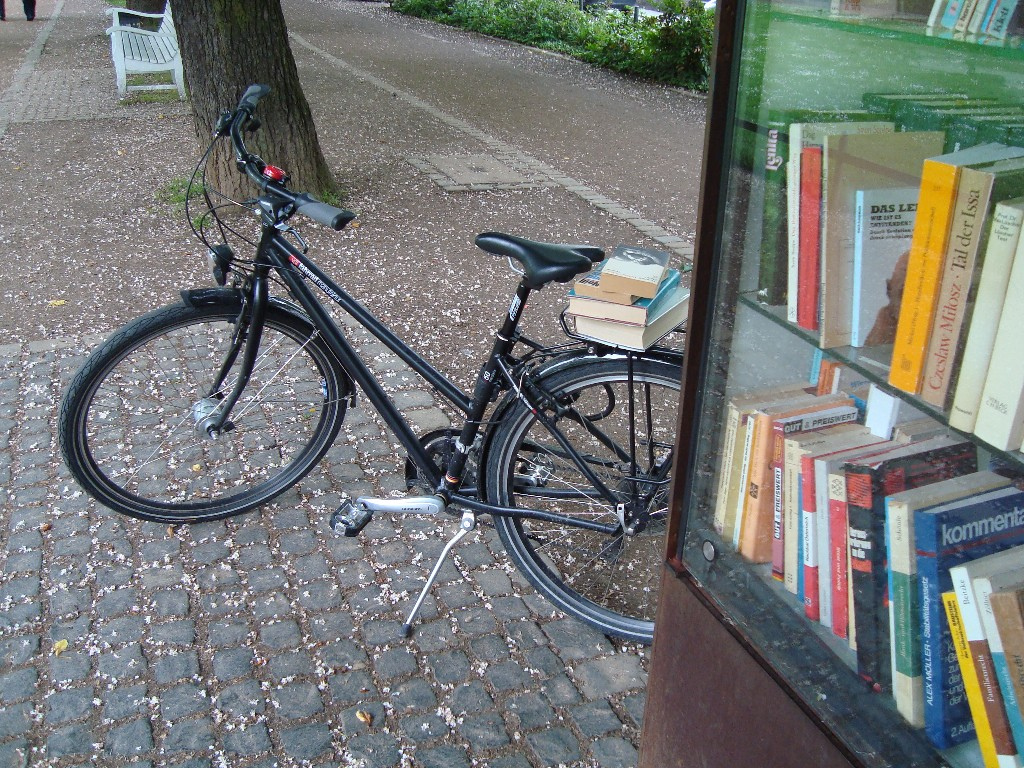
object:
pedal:
[329, 495, 444, 538]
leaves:
[0, 0, 712, 768]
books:
[712, 91, 1024, 768]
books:
[564, 243, 690, 353]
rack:
[559, 305, 687, 357]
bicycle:
[58, 82, 690, 644]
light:
[265, 165, 285, 182]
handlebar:
[230, 84, 354, 231]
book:
[988, 582, 1024, 716]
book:
[829, 473, 849, 638]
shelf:
[677, 525, 956, 767]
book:
[818, 130, 946, 349]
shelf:
[737, 289, 1024, 467]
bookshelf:
[640, 0, 1024, 767]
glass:
[677, 0, 1024, 768]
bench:
[106, 1, 189, 101]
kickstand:
[397, 510, 476, 638]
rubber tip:
[399, 623, 413, 638]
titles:
[714, 347, 1024, 766]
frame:
[266, 236, 545, 494]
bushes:
[389, 0, 720, 95]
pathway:
[285, 0, 710, 262]